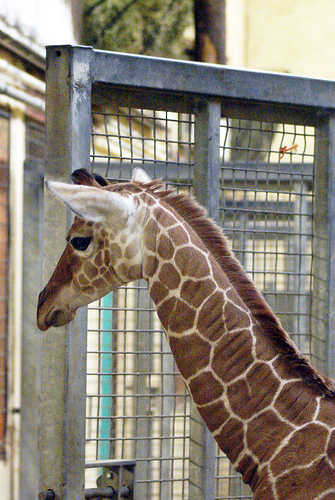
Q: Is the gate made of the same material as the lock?
A: Yes, both the gate and the lock are made of metal.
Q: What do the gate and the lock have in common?
A: The material, both the gate and the lock are metallic.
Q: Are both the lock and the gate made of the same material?
A: Yes, both the lock and the gate are made of metal.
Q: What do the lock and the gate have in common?
A: The material, both the lock and the gate are metallic.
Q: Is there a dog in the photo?
A: No, there are no dogs.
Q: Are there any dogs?
A: No, there are no dogs.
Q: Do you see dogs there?
A: No, there are no dogs.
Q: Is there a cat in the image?
A: No, there are no cats.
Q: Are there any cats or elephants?
A: No, there are no cats or elephants.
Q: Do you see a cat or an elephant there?
A: No, there are no cats or elephants.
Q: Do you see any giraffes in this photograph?
A: Yes, there is a giraffe.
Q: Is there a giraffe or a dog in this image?
A: Yes, there is a giraffe.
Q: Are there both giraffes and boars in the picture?
A: No, there is a giraffe but no boars.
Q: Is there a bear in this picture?
A: No, there are no bears.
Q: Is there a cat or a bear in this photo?
A: No, there are no bears or cats.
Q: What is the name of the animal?
A: The animal is a giraffe.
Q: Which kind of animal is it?
A: The animal is a giraffe.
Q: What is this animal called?
A: This is a giraffe.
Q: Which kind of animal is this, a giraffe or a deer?
A: This is a giraffe.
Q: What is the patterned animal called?
A: The animal is a giraffe.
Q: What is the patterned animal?
A: The animal is a giraffe.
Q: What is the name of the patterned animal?
A: The animal is a giraffe.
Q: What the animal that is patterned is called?
A: The animal is a giraffe.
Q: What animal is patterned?
A: The animal is a giraffe.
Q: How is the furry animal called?
A: The animal is a giraffe.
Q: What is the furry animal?
A: The animal is a giraffe.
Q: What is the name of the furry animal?
A: The animal is a giraffe.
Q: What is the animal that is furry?
A: The animal is a giraffe.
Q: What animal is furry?
A: The animal is a giraffe.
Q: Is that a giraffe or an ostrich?
A: That is a giraffe.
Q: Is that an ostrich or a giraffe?
A: That is a giraffe.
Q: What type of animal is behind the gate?
A: The animal is a giraffe.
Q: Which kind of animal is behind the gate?
A: The animal is a giraffe.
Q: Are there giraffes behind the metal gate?
A: Yes, there is a giraffe behind the gate.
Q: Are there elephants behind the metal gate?
A: No, there is a giraffe behind the gate.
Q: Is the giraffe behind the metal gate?
A: Yes, the giraffe is behind the gate.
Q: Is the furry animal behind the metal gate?
A: Yes, the giraffe is behind the gate.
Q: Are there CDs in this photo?
A: No, there are no cds.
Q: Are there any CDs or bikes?
A: No, there are no CDs or bikes.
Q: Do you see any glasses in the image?
A: No, there are no glasses.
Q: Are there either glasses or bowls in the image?
A: No, there are no glasses or bowls.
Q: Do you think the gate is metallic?
A: Yes, the gate is metallic.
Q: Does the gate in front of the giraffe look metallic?
A: Yes, the gate is metallic.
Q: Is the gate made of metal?
A: Yes, the gate is made of metal.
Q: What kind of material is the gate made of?
A: The gate is made of metal.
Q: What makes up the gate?
A: The gate is made of metal.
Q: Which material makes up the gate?
A: The gate is made of metal.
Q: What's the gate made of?
A: The gate is made of metal.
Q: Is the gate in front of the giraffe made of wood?
A: No, the gate is made of metal.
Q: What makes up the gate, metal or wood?
A: The gate is made of metal.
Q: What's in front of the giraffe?
A: The gate is in front of the giraffe.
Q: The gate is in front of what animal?
A: The gate is in front of the giraffe.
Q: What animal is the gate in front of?
A: The gate is in front of the giraffe.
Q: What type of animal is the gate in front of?
A: The gate is in front of the giraffe.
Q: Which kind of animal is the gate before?
A: The gate is in front of the giraffe.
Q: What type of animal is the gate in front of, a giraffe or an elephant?
A: The gate is in front of a giraffe.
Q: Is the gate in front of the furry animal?
A: Yes, the gate is in front of the giraffe.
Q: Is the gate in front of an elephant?
A: No, the gate is in front of the giraffe.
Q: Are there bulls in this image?
A: No, there are no bulls.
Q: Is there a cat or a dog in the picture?
A: No, there are no dogs or cats.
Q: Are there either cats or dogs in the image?
A: No, there are no dogs or cats.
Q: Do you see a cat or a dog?
A: No, there are no dogs or cats.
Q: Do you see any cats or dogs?
A: No, there are no dogs or cats.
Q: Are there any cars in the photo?
A: No, there are no cars.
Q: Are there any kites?
A: No, there are no kites.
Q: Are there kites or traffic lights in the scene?
A: No, there are no kites or traffic lights.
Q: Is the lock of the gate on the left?
A: Yes, the lock is on the left of the image.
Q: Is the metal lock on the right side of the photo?
A: No, the lock is on the left of the image.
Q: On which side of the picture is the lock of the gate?
A: The lock is on the left of the image.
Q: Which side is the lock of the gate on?
A: The lock is on the left of the image.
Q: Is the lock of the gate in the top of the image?
A: No, the lock is in the bottom of the image.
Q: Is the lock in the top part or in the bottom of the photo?
A: The lock is in the bottom of the image.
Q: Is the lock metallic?
A: Yes, the lock is metallic.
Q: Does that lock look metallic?
A: Yes, the lock is metallic.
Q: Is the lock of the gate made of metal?
A: Yes, the lock is made of metal.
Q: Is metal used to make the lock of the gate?
A: Yes, the lock is made of metal.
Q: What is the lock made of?
A: The lock is made of metal.